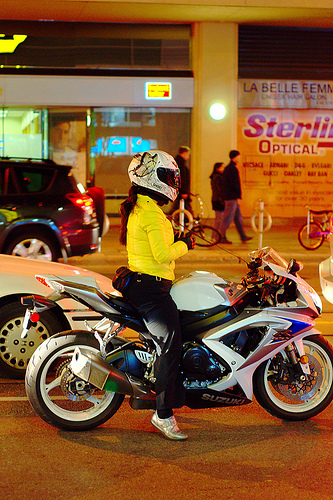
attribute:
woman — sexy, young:
[111, 145, 194, 443]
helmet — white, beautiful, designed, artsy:
[124, 148, 181, 203]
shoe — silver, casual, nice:
[148, 408, 188, 443]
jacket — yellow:
[124, 191, 188, 282]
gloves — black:
[173, 228, 197, 253]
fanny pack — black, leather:
[111, 266, 136, 295]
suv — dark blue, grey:
[0, 154, 104, 263]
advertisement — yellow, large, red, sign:
[237, 107, 332, 218]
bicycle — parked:
[169, 194, 221, 249]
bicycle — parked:
[295, 205, 332, 249]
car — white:
[0, 253, 122, 379]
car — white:
[317, 250, 332, 306]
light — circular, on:
[207, 99, 228, 123]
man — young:
[173, 146, 195, 225]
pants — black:
[120, 271, 186, 413]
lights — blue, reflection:
[90, 133, 152, 157]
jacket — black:
[172, 155, 191, 200]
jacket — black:
[222, 160, 243, 202]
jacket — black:
[209, 168, 224, 210]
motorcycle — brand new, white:
[24, 261, 331, 420]